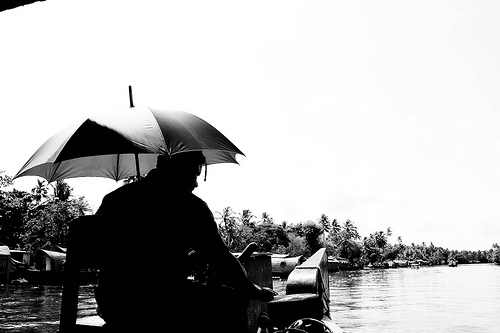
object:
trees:
[0, 185, 499, 275]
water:
[329, 270, 498, 330]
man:
[82, 150, 279, 333]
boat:
[50, 246, 336, 333]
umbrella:
[10, 83, 246, 185]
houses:
[220, 206, 500, 272]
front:
[265, 244, 336, 332]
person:
[76, 151, 278, 332]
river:
[326, 264, 496, 330]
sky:
[0, 0, 500, 191]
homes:
[231, 248, 422, 274]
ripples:
[0, 283, 110, 332]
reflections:
[333, 267, 405, 314]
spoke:
[239, 150, 247, 159]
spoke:
[165, 149, 176, 161]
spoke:
[49, 158, 62, 168]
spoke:
[7, 175, 17, 183]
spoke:
[46, 179, 53, 186]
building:
[0, 0, 40, 18]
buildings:
[262, 253, 436, 272]